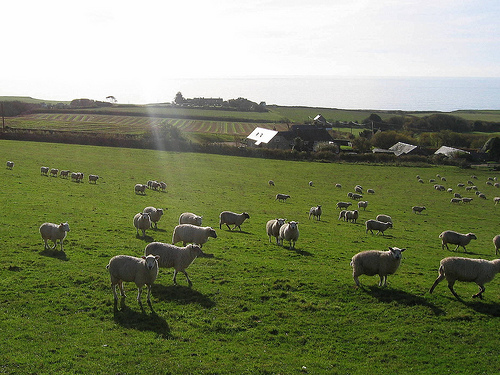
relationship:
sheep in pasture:
[36, 193, 235, 291] [5, 137, 498, 374]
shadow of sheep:
[111, 282, 211, 343] [36, 193, 235, 291]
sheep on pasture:
[36, 193, 235, 291] [5, 137, 498, 374]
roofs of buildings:
[398, 143, 460, 153] [383, 134, 489, 159]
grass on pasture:
[227, 276, 498, 373] [5, 137, 498, 374]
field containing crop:
[26, 109, 295, 139] [218, 120, 230, 132]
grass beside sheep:
[227, 276, 498, 373] [36, 193, 235, 291]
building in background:
[246, 123, 288, 148] [8, 114, 499, 121]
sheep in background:
[36, 193, 235, 291] [8, 114, 499, 121]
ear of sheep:
[56, 221, 64, 228] [39, 219, 72, 253]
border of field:
[1, 125, 477, 166] [26, 109, 295, 139]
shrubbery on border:
[69, 131, 182, 148] [1, 125, 477, 166]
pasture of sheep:
[5, 137, 498, 374] [36, 193, 235, 291]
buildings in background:
[383, 134, 489, 159] [8, 114, 499, 121]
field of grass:
[26, 109, 295, 139] [227, 276, 498, 373]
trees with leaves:
[364, 112, 489, 133] [425, 116, 438, 119]